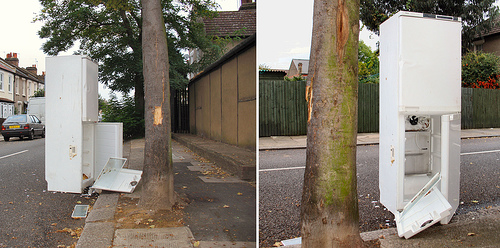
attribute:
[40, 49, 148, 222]
refrigerator — old, white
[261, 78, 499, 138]
fence — big, green, is tall, is green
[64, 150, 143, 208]
pieces — are white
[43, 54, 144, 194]
fridge — is broken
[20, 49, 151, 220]
refrigerator — broken, white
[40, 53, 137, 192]
refrigerator — white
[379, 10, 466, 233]
refrigerator — old, white, sitting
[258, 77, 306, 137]
fencing — tall, green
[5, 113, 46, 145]
car — parked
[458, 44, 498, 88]
bush — is beautiful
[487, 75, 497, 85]
roses — is beautiful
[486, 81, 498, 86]
roses — is beautiful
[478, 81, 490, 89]
roses — is beautiful